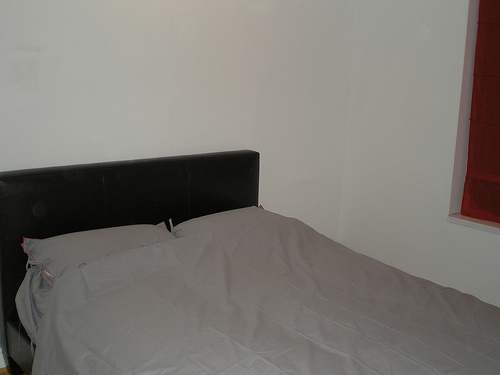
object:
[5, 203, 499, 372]
comforter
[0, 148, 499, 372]
bed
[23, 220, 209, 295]
pillows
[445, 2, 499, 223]
window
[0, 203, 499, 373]
blanket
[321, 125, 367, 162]
ground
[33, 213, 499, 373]
bedsheet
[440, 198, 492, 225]
ledge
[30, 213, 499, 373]
cover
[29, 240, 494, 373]
fabric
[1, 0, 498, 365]
room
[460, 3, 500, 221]
curtain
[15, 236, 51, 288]
stitching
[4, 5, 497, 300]
wall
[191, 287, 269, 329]
creases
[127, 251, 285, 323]
frabric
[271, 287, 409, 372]
frabric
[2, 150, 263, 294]
headboard